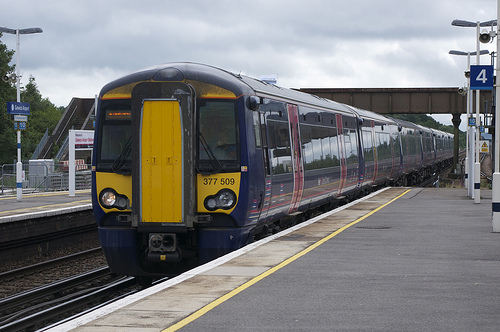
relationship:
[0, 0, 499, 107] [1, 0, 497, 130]
cloud in sky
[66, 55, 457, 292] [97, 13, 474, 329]
passenger train sitting at train station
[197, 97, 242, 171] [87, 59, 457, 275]
windshield on train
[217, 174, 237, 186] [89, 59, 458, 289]
number on passenger train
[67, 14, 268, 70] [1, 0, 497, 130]
cloud in sky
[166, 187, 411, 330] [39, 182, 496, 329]
line on platform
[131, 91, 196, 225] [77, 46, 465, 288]
door on train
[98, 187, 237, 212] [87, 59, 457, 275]
headlights on train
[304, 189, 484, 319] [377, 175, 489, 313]
crosswalk near platform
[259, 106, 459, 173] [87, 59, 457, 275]
window on train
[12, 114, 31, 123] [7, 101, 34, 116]
sign on sign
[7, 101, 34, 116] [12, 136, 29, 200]
sign on pole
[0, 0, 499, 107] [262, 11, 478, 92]
cloud in sky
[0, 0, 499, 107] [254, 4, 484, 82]
cloud in sky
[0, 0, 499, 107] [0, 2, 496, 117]
cloud in sky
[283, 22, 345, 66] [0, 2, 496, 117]
clouds in sky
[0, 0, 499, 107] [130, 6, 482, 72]
cloud in sky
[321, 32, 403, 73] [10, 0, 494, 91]
clouds in sky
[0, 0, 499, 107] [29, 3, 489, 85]
cloud in sky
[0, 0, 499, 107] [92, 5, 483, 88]
cloud in sky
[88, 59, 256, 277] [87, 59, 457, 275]
front end of train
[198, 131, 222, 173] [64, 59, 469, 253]
windshield wiper on left side of train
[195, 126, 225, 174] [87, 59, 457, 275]
windshield wiper on right side of train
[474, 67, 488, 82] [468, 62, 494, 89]
number 4 on sign